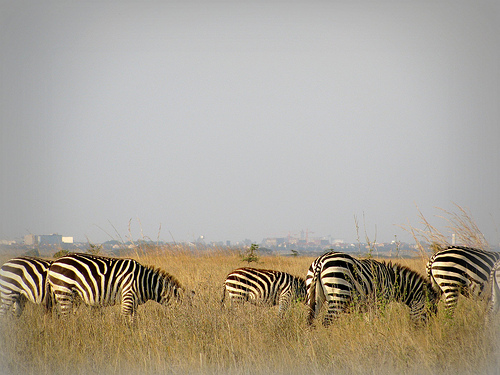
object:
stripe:
[51, 285, 74, 315]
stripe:
[79, 258, 99, 297]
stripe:
[115, 258, 136, 300]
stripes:
[302, 250, 437, 333]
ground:
[28, 328, 438, 375]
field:
[1, 250, 498, 374]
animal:
[0, 255, 55, 318]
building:
[0, 233, 72, 245]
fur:
[336, 259, 377, 298]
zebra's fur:
[433, 250, 499, 292]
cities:
[12, 233, 486, 251]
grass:
[1, 200, 498, 372]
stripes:
[224, 266, 304, 308]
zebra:
[220, 267, 305, 315]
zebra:
[303, 249, 440, 333]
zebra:
[425, 245, 500, 319]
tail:
[304, 262, 322, 328]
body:
[305, 253, 393, 327]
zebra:
[40, 252, 196, 322]